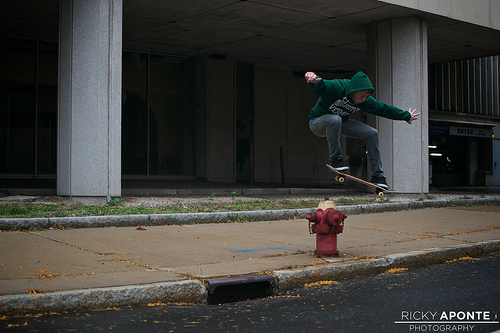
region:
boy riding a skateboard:
[260, 42, 416, 207]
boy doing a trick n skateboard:
[282, 64, 397, 208]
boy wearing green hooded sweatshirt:
[292, 44, 402, 201]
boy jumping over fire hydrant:
[277, 47, 409, 202]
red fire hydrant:
[298, 193, 350, 253]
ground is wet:
[17, 205, 493, 296]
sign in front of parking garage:
[447, 116, 498, 143]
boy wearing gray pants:
[286, 45, 413, 214]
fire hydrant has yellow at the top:
[301, 189, 354, 261]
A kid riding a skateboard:
[300, 70, 415, 197]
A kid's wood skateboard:
[325, 160, 390, 195]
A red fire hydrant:
[305, 195, 347, 255]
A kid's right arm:
[322, 77, 345, 94]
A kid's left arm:
[370, 96, 410, 122]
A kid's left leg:
[342, 117, 382, 171]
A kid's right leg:
[307, 115, 344, 155]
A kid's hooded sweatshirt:
[307, 71, 409, 130]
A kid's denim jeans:
[310, 113, 381, 170]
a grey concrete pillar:
[56, 0, 121, 196]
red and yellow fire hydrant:
[291, 192, 358, 266]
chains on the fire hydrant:
[290, 187, 349, 266]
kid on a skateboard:
[297, 45, 427, 215]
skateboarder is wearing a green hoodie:
[290, 58, 427, 210]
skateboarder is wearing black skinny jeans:
[308, 108, 390, 196]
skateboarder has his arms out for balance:
[289, 53, 429, 216]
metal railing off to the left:
[420, 47, 497, 147]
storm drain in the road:
[190, 259, 291, 312]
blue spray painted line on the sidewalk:
[195, 223, 368, 275]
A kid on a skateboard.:
[302, 70, 422, 200]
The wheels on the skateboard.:
[333, 173, 343, 183]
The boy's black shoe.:
[326, 154, 348, 173]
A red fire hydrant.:
[304, 197, 346, 259]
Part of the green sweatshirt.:
[331, 83, 340, 98]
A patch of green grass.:
[1, 202, 26, 219]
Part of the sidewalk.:
[149, 234, 186, 262]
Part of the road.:
[362, 304, 391, 325]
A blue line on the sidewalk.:
[232, 244, 294, 254]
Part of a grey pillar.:
[73, 94, 110, 194]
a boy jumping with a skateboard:
[298, 51, 415, 206]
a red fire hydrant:
[301, 189, 361, 264]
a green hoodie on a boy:
[301, 58, 423, 148]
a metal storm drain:
[193, 258, 280, 315]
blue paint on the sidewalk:
[220, 236, 311, 266]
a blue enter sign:
[451, 116, 481, 141]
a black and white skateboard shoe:
[373, 165, 391, 205]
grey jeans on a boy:
[310, 103, 390, 183]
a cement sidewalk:
[0, 207, 497, 297]